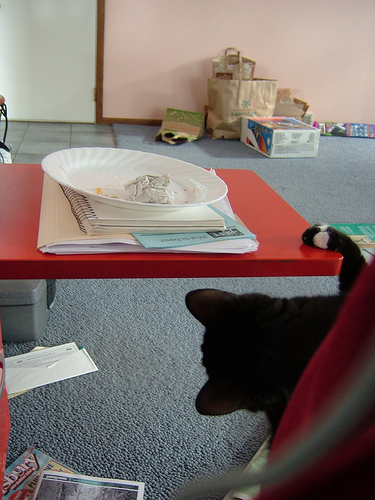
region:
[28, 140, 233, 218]
empty white plate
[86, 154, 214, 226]
used crumpled up napkins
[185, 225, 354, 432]
playing black cat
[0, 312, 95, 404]
check in envelope lying on floor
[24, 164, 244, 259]
spiral notebook lying under plate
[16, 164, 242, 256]
folder with papers lying under notebook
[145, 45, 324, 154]
several brown carry bags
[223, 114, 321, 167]
cardboard box lying on floor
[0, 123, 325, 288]
orange table with papers lying on it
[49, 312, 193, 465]
beautiful gray short carpet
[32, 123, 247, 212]
a white plate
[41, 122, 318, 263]
a white plate on a pile of papers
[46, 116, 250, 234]
a crumpled napkin on a plate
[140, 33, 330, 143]
paper bags on the floor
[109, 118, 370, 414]
a grey carpet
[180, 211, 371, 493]
a cat leans down to look under the table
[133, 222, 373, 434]
the cat's paw is holding the table corner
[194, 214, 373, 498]
the cat is black and white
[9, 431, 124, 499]
there are newspapers on the floor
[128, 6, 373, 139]
the walls are light pink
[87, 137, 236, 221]
Napkin on a paper plate.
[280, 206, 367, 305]
Cats paw on table.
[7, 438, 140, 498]
Magazines on the floor.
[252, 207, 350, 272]
Black and white cats paw.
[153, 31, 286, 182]
Grocery bags on the floor.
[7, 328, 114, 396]
Mail on the floor.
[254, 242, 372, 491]
Red and gray blanket.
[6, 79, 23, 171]
A mettel and wooden stool.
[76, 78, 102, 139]
Small metal door hinges.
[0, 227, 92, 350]
Gray tackle box under table.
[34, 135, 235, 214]
White plate on stack of stuff.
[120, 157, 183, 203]
Balled up napkin on a plate.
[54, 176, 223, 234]
Opened notebook under plate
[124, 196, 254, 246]
Blue paper under notebook.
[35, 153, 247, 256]
Folder on bottom of stack.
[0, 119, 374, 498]
The carpet is light blue.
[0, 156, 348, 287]
The table top is orange.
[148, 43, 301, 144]
There's paper bags against wall.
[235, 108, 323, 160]
There's a box lying on floor.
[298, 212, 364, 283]
Cat's paw is on the table.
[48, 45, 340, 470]
a room with personal belongings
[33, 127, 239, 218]
empty plate with a rumpled napkin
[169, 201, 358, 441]
cat leaning sideways under desk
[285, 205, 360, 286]
black paw with white markings on corner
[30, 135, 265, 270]
notebook between folder and plate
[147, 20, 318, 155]
box and shopping bags against wall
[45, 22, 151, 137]
different walls and flooring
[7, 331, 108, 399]
envelope with contents sticking out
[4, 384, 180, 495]
magazines on top of blue carpeting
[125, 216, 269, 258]
folded blue paper inserted in notebook